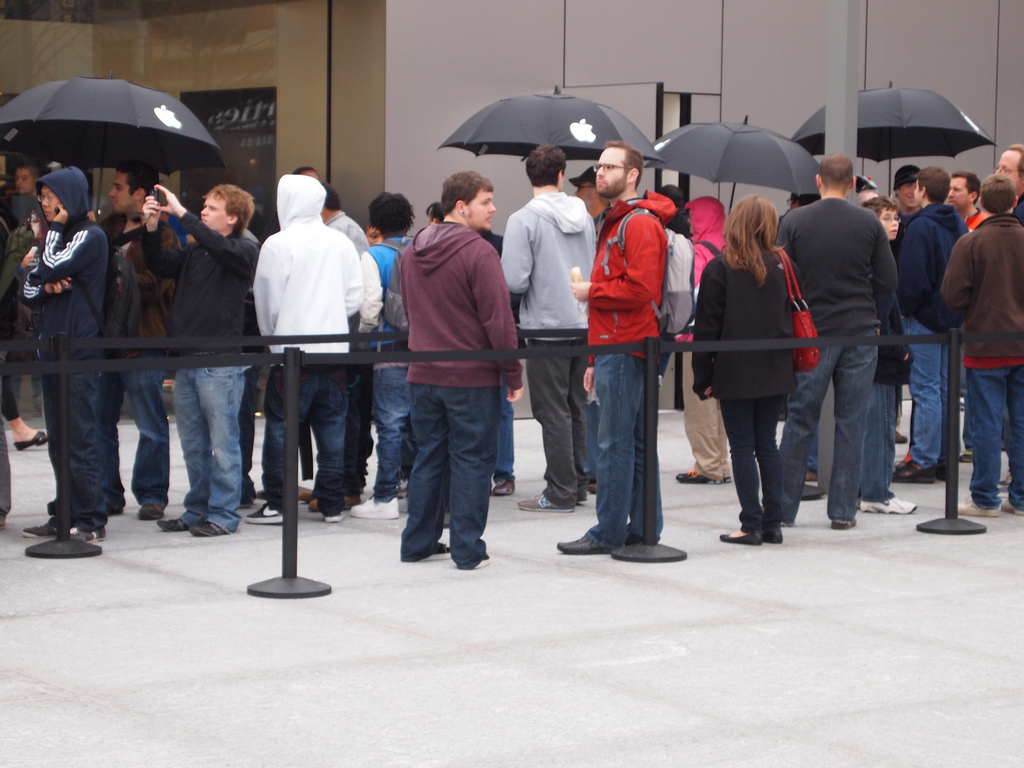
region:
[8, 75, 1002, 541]
People standing in a line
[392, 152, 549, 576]
Man wearing a purple hoodie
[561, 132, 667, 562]
Man wearing a red coat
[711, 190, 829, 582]
Woman with a red purse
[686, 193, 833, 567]
Woman in a black coat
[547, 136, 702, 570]
Man wearing gray backpack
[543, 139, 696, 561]
Man holding piece of food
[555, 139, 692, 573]
Man wearing blue jeans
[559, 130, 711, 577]
Man with a trimmed beard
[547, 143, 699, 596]
Man wearing small glasses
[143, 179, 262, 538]
Person taking a picture.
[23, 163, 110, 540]
Person wearing hoodie talking on phone.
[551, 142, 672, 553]
Man in red jacket.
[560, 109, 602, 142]
Apple computer logo in white.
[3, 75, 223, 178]
Black umbrella with white logo.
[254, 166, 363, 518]
Back of person wearing white, hooded jacket.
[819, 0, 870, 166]
A gray, four sided pole.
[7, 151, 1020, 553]
People standing in line.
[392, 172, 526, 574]
A man standing, looking to the right.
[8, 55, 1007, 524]
People waiting in a line.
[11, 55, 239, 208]
A black umbrella.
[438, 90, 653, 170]
An umbrella with a white apple logo on it.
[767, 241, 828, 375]
A red shoulder bag.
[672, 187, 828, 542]
A woman with a red shoulder bag.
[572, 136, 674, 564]
A man in a red jacket.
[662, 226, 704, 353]
A white and grey backpack.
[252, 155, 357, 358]
A person wearing a white hoodie.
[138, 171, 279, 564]
A person taking a picture.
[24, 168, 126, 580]
A person talking on a cellphone.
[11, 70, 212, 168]
black umbrella with an Apple logo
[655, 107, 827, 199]
black umbrella with an Apple logo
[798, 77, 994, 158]
black umbrella with an Apple logo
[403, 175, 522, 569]
man in a purple sweatshirt standing on line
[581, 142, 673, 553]
man in a red jacket standing on line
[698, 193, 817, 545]
woman dressed in black standing on line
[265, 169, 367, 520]
young person in a white sweatshirt standing on line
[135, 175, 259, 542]
young man in a black coat taking a picture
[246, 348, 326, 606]
pole holding the line dividers